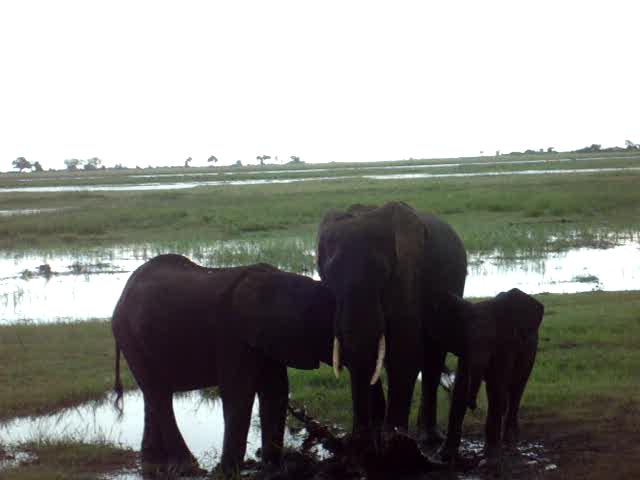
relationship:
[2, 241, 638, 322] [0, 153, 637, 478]
water on grass